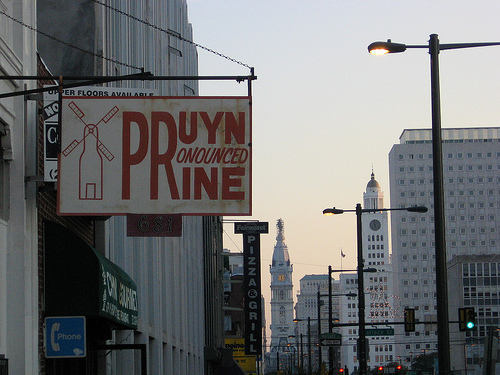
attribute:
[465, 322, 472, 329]
light — green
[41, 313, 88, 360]
sign — blue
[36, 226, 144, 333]
canopy — dark green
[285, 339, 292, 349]
light — overhead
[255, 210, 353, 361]
tower — tall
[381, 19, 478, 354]
light — overhead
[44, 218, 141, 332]
canopy — green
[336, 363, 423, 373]
streelights — red 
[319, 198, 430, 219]
light — overhead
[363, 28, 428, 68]
light — overhead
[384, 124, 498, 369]
skyscraper — white, tall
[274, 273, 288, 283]
window — illuminated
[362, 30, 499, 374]
lamp post — black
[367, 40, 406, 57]
street light — lit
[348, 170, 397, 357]
clocktower — tall